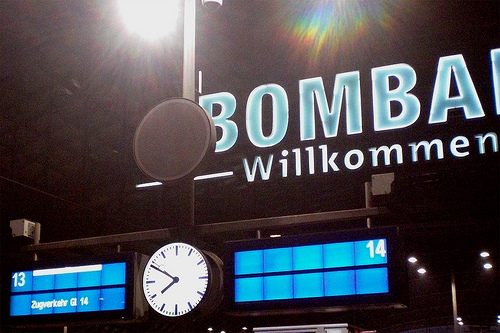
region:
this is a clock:
[120, 226, 233, 317]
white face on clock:
[125, 228, 235, 318]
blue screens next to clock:
[5, 216, 407, 310]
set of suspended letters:
[220, 125, 492, 205]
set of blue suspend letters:
[152, 35, 497, 160]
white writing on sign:
[20, 285, 107, 324]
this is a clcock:
[118, 217, 238, 327]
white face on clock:
[123, 229, 225, 323]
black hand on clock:
[137, 223, 206, 315]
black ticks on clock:
[132, 238, 219, 316]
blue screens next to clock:
[3, 238, 451, 323]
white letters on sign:
[23, 288, 100, 316]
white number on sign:
[348, 228, 395, 276]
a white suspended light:
[230, 120, 497, 205]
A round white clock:
[142, 240, 209, 313]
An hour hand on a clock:
[155, 278, 172, 295]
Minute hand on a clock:
[149, 260, 173, 278]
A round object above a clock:
[134, 97, 214, 182]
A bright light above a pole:
[109, 3, 182, 48]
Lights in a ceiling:
[402, 253, 426, 275]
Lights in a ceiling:
[476, 248, 491, 269]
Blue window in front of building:
[227, 235, 397, 302]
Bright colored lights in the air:
[281, 5, 407, 67]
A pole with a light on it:
[182, 3, 197, 100]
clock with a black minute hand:
[148, 261, 177, 283]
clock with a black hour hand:
[158, 276, 178, 293]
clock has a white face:
[141, 242, 208, 317]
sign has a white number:
[220, 223, 409, 318]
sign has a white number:
[3, 252, 148, 331]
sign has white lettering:
[29, 299, 70, 309]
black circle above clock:
[130, 96, 217, 187]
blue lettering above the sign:
[182, 45, 498, 152]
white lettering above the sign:
[240, 130, 498, 187]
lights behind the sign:
[404, 253, 426, 274]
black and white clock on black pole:
[137, 240, 220, 320]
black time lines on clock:
[142, 240, 208, 319]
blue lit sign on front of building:
[131, 42, 497, 192]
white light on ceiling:
[104, 0, 196, 80]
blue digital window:
[5, 232, 396, 324]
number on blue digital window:
[8, 270, 30, 291]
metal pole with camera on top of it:
[166, 0, 232, 225]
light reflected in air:
[272, 1, 407, 70]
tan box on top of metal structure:
[6, 213, 42, 241]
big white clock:
[142, 243, 213, 316]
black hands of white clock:
[148, 263, 178, 295]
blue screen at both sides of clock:
[13, 238, 388, 317]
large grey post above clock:
[177, 2, 199, 220]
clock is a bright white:
[134, 242, 212, 319]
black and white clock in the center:
[141, 240, 209, 317]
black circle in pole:
[133, 97, 218, 191]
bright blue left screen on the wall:
[5, 268, 133, 316]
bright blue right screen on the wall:
[230, 240, 399, 295]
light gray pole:
[180, 3, 200, 94]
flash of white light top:
[113, 3, 182, 46]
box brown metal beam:
[13, 210, 47, 242]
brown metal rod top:
[25, 205, 390, 239]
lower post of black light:
[176, 180, 201, 227]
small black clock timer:
[151, 263, 176, 283]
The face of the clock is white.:
[123, 241, 220, 316]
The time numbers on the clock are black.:
[149, 276, 191, 314]